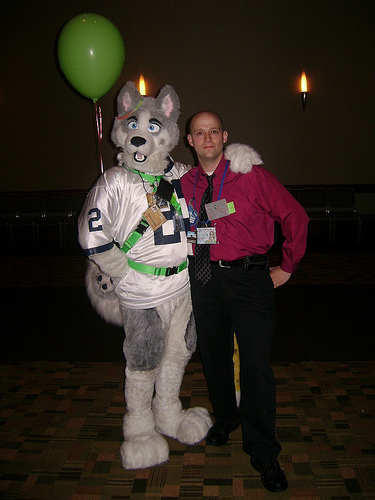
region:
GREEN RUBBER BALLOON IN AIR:
[40, 9, 140, 131]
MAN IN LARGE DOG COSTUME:
[69, 99, 230, 448]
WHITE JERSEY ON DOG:
[112, 171, 199, 316]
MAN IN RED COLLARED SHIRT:
[174, 126, 304, 362]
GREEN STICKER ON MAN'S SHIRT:
[225, 200, 240, 218]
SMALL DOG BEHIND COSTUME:
[82, 264, 133, 325]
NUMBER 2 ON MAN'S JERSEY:
[77, 203, 125, 248]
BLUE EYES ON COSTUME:
[122, 111, 180, 153]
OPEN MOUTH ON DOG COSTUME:
[126, 133, 144, 159]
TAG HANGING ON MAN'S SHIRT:
[197, 209, 234, 268]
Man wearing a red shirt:
[176, 106, 307, 490]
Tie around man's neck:
[193, 171, 221, 284]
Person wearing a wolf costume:
[75, 76, 222, 474]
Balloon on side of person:
[36, 12, 126, 190]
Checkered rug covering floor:
[0, 356, 373, 498]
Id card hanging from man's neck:
[190, 164, 226, 248]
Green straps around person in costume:
[120, 162, 189, 283]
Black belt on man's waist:
[187, 252, 274, 273]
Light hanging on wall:
[279, 65, 315, 117]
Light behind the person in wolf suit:
[125, 59, 162, 111]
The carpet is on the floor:
[23, 390, 104, 471]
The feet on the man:
[208, 408, 293, 496]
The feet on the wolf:
[105, 405, 217, 470]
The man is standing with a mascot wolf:
[83, 75, 312, 467]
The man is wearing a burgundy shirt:
[181, 157, 312, 279]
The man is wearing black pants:
[183, 258, 292, 460]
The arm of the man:
[255, 166, 311, 266]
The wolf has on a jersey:
[77, 158, 203, 309]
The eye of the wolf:
[144, 116, 163, 138]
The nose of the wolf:
[128, 133, 149, 152]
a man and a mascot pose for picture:
[75, 79, 310, 493]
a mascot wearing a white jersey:
[70, 77, 261, 472]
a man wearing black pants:
[189, 256, 281, 462]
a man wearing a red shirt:
[178, 154, 310, 275]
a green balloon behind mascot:
[56, 10, 127, 172]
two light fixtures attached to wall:
[134, 65, 312, 120]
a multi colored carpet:
[0, 359, 372, 498]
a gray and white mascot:
[75, 78, 265, 469]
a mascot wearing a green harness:
[118, 157, 191, 279]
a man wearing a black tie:
[193, 172, 217, 285]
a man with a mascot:
[63, 55, 320, 299]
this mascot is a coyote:
[71, 69, 203, 311]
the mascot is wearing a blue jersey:
[48, 141, 200, 288]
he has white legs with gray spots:
[90, 275, 207, 474]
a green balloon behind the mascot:
[45, 1, 176, 174]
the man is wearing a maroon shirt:
[177, 108, 306, 380]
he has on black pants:
[177, 236, 294, 418]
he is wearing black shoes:
[193, 402, 293, 498]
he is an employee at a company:
[190, 174, 233, 254]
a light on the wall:
[272, 62, 338, 122]